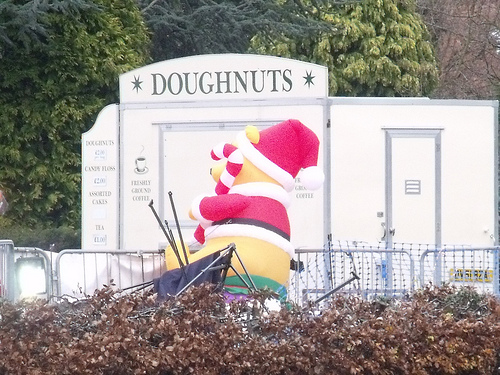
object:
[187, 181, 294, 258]
red jacket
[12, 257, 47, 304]
mirror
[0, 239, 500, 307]
fence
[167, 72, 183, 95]
letter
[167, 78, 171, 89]
black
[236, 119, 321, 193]
hat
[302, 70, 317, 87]
star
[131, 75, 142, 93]
star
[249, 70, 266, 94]
letter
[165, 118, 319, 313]
balloon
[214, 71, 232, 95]
letter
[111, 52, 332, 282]
sign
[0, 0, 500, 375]
picture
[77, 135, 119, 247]
writing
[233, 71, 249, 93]
letter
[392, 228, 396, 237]
handle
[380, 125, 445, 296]
door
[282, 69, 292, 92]
black letter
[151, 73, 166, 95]
letter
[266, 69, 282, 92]
letter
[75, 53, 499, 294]
building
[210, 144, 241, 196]
candy